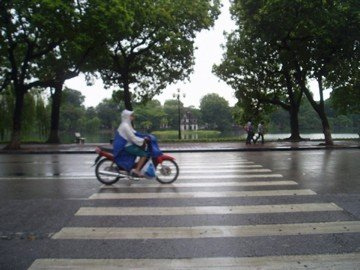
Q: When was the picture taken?
A: Daytime.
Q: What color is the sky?
A: White.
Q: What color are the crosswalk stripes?
A: White.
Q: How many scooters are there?
A: One.